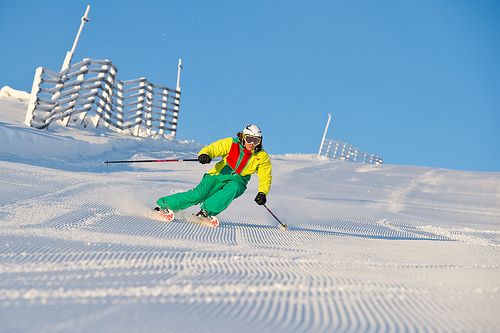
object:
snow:
[0, 85, 499, 332]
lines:
[43, 178, 108, 197]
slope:
[0, 152, 499, 333]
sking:
[190, 212, 220, 229]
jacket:
[196, 137, 273, 194]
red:
[226, 151, 235, 166]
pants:
[155, 169, 249, 218]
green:
[204, 179, 236, 202]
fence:
[25, 58, 184, 131]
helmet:
[239, 123, 265, 149]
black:
[244, 125, 254, 134]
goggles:
[242, 132, 261, 147]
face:
[244, 136, 261, 150]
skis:
[152, 204, 176, 223]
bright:
[0, 0, 499, 174]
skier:
[154, 123, 274, 223]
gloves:
[197, 151, 212, 166]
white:
[215, 218, 223, 229]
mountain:
[0, 91, 498, 333]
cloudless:
[0, 1, 499, 175]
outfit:
[155, 138, 273, 215]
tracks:
[233, 223, 246, 245]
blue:
[184, 1, 486, 100]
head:
[239, 123, 263, 152]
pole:
[101, 158, 210, 163]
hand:
[194, 152, 214, 166]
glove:
[252, 191, 269, 207]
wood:
[174, 57, 182, 137]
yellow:
[258, 161, 270, 188]